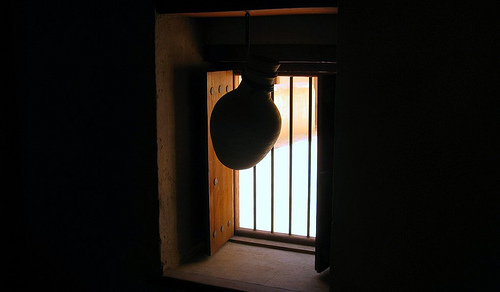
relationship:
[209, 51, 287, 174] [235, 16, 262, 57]
object on rope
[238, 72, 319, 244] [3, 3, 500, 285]
window in wall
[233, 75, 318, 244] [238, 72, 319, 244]
bars on window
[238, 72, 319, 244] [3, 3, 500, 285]
window on wall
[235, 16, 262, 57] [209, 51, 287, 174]
rope hanging object